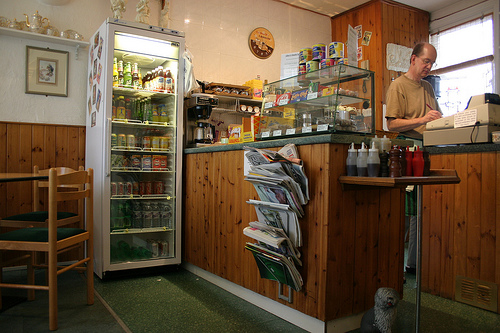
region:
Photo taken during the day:
[7, 6, 488, 323]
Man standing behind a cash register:
[380, 0, 462, 260]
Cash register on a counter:
[429, 106, 496, 166]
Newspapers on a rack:
[211, 127, 323, 319]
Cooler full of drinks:
[72, 17, 220, 291]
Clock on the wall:
[237, 25, 283, 62]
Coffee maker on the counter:
[183, 83, 229, 157]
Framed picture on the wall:
[14, 38, 92, 114]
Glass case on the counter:
[214, 56, 392, 145]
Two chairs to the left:
[14, 153, 121, 323]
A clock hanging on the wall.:
[235, 19, 278, 62]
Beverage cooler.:
[76, 17, 196, 282]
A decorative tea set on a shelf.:
[2, 8, 87, 54]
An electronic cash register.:
[413, 92, 499, 149]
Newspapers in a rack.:
[224, 142, 321, 229]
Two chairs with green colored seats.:
[8, 167, 101, 329]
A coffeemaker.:
[187, 92, 218, 149]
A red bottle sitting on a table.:
[409, 142, 431, 179]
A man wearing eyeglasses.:
[386, 34, 445, 103]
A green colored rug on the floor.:
[98, 285, 230, 327]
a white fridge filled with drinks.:
[86, 8, 213, 281]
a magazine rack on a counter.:
[233, 141, 329, 293]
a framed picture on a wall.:
[13, 42, 80, 101]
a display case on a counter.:
[240, 43, 400, 140]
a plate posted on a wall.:
[240, 21, 285, 59]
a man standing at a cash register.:
[370, 28, 458, 162]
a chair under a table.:
[0, 146, 132, 332]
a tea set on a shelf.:
[0, 3, 100, 55]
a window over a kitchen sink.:
[398, 13, 498, 126]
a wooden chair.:
[3, 161, 109, 327]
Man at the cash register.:
[383, 37, 498, 150]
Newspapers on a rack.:
[237, 141, 314, 306]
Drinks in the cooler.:
[83, 19, 190, 278]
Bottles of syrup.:
[346, 136, 381, 179]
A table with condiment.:
[340, 126, 460, 192]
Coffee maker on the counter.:
[181, 98, 217, 148]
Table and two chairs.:
[1, 157, 96, 329]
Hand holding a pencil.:
[420, 97, 445, 123]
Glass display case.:
[253, 61, 380, 146]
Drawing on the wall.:
[21, 41, 71, 102]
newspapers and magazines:
[240, 145, 315, 295]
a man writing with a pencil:
[384, 34, 443, 126]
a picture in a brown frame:
[22, 41, 74, 105]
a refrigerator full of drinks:
[89, 22, 188, 270]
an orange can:
[151, 152, 161, 167]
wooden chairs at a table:
[2, 165, 97, 330]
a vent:
[454, 273, 496, 310]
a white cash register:
[424, 95, 497, 143]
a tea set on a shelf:
[0, 3, 87, 43]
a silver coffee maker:
[187, 93, 217, 145]